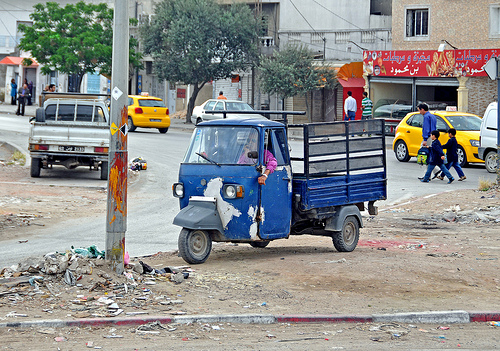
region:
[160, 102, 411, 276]
a vehicle with three wheels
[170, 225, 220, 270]
front wheel of vehicle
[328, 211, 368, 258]
back wheel of vehicle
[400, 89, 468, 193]
man holding two kids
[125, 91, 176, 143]
the car is color yellow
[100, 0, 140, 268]
the pole is color gray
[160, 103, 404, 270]
person inside the vehicle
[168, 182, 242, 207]
two headlights of vehicle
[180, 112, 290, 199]
person inside the vehicle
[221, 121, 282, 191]
person wears pink clothes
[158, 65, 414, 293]
this is a truck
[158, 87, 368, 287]
the truck is blue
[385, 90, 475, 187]
this is a car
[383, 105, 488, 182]
the car is yellow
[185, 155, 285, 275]
paint missing on the truck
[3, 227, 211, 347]
debris on the ground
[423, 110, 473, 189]
kids on the street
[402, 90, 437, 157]
man on the street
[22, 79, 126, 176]
this is a grey truck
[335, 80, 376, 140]
people walking on side of street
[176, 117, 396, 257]
The truck is blue.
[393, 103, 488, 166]
The car is yellow.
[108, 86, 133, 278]
The pole has paint on it.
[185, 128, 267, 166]
The windshield is clean.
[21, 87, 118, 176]
The truck is grey.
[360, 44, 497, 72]
The sign is red.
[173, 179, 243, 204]
The lights are off.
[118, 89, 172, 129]
The taxi is yellow.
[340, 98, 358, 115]
His shirt is blue.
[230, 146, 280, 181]
His shirt is purple.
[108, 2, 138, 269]
the street pole is rusty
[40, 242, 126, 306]
garbage under the street pole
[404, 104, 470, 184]
the man with two boys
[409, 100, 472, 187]
the man crossing the street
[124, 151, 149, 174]
garbage in the street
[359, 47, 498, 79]
the sign on the building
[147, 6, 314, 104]
trees beside the street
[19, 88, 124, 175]
the pickup truck on the street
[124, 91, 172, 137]
yellow taxi on the street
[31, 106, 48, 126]
the tire in the pickup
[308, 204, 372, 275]
the wheel is black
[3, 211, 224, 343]
garbage at the base of the pole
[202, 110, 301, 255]
a man is in the truck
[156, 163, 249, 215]
the headlights are off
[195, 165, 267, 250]
the paint is peeling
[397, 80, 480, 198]
people are walking in the street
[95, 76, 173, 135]
the cab is yellow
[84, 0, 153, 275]
the pole is grey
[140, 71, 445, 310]
the truck is parked